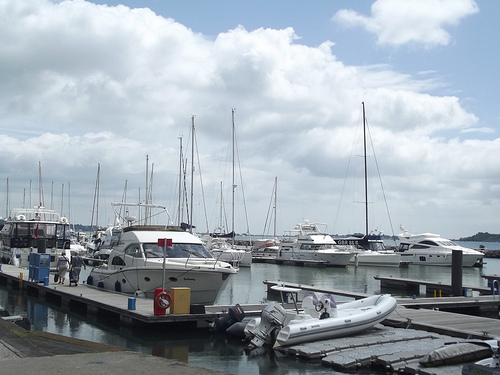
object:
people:
[71, 252, 86, 280]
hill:
[451, 232, 500, 243]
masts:
[231, 109, 237, 231]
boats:
[87, 203, 236, 306]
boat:
[205, 294, 396, 363]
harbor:
[0, 197, 500, 375]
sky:
[0, 0, 500, 238]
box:
[170, 287, 190, 313]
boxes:
[34, 254, 50, 281]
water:
[0, 237, 500, 375]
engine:
[247, 300, 287, 349]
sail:
[117, 180, 127, 228]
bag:
[419, 339, 498, 366]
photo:
[0, 0, 500, 375]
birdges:
[0, 264, 215, 324]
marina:
[0, 264, 500, 375]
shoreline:
[305, 236, 500, 245]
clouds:
[330, 0, 480, 49]